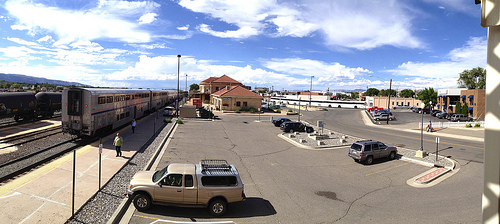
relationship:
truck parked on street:
[125, 155, 251, 219] [130, 111, 469, 223]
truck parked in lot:
[125, 155, 251, 219] [130, 111, 469, 223]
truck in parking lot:
[125, 155, 251, 219] [130, 111, 469, 223]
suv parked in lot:
[125, 155, 251, 219] [130, 111, 469, 223]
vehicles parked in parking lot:
[366, 102, 396, 124] [366, 105, 436, 124]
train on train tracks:
[57, 82, 189, 139] [1, 126, 65, 183]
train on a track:
[57, 82, 189, 139] [1, 126, 65, 183]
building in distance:
[253, 85, 272, 98] [237, 79, 476, 96]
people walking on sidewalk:
[110, 129, 127, 160] [64, 124, 130, 224]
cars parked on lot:
[366, 102, 396, 124] [366, 105, 436, 124]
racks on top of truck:
[198, 156, 233, 174] [125, 155, 251, 219]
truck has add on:
[125, 155, 251, 219] [198, 152, 242, 188]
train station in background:
[0, 89, 64, 124] [0, 78, 67, 100]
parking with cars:
[366, 105, 436, 124] [366, 102, 396, 124]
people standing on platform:
[110, 116, 141, 157] [90, 116, 144, 181]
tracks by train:
[1, 126, 65, 183] [57, 82, 189, 139]